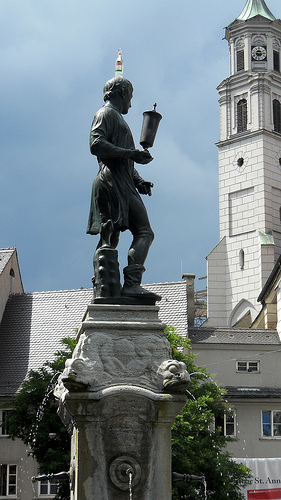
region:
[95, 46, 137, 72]
Bottle on a statue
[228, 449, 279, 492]
Sign on a building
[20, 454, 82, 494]
water coming out of statue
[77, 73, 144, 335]
Statue of a man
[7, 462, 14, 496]
White frame window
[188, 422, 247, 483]
tree behind a statue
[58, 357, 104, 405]
lizard face on a statue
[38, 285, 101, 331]
shingles on a roof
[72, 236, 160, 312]
man on statue with boots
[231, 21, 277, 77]
clock on a building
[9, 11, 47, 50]
white clouds in blue sky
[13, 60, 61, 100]
white clouds in blue sky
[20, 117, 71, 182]
white clouds in blue sky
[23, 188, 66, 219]
white clouds in blue sky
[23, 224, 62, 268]
white clouds in blue sky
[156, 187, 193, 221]
white clouds in blue sky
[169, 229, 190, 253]
white clouds in blue sky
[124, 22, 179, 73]
white clouds in blue sky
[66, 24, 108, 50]
white clouds in blue sky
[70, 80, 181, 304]
statue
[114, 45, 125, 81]
a bottle on top of a statue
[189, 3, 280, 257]
a tall clock tower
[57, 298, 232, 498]
a fountain under a statue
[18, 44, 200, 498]
a statue on top of a fountain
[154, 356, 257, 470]
Water spraying out of a fountain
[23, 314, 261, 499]
a tree behind a fountain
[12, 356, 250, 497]
Water spraying from multiple places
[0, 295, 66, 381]
A roof on a building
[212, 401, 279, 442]
Windows on a building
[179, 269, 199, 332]
A chimney on a building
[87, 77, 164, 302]
dark statue of a man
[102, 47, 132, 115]
bottle high on statue's head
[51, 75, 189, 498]
fountain beneath statue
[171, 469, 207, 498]
water pouring from fountain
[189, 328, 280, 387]
small window near roof of building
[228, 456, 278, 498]
part of a red and white banner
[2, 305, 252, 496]
tree behind fountain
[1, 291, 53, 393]
shadow falling across roof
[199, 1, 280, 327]
large tower composed of white blocks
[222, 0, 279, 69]
clock near top of tower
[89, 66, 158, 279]
dark gray statue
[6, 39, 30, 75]
white clouds in blue sky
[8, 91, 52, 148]
white clouds in blue sky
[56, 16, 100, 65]
white clouds in blue sky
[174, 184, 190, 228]
white clouds in blue sky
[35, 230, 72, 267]
vwhite clouds in blue sky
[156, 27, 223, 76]
white clouds in blue sky